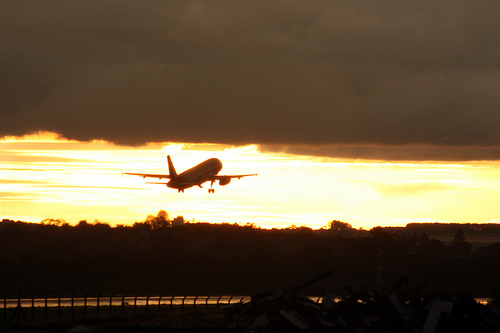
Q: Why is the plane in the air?
A: Taking off.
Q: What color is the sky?
A: Orange.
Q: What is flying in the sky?
A: A plane.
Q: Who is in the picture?
A: No one.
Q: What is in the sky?
A: Clouds.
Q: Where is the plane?
A: In the air.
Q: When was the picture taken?
A: Sunset.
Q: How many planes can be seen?
A: 1.